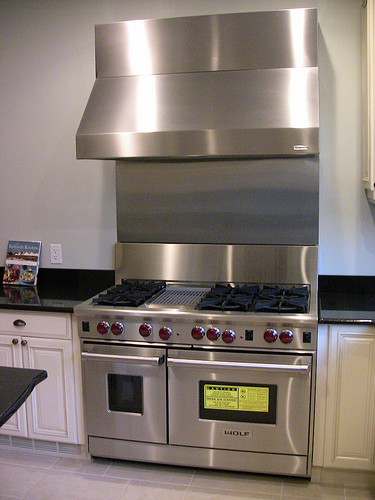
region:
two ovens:
[89, 342, 320, 434]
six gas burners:
[127, 265, 320, 353]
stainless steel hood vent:
[105, 100, 326, 193]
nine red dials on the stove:
[87, 317, 295, 350]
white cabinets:
[5, 335, 78, 455]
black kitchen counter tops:
[7, 355, 63, 422]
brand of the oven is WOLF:
[209, 405, 262, 450]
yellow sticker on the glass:
[193, 380, 300, 413]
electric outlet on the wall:
[35, 237, 75, 269]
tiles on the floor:
[68, 452, 138, 497]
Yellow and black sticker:
[197, 374, 299, 439]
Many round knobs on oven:
[96, 314, 303, 353]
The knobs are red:
[85, 314, 300, 352]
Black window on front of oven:
[95, 361, 161, 426]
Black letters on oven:
[208, 413, 271, 443]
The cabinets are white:
[5, 308, 113, 455]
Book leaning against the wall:
[2, 235, 53, 297]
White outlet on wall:
[40, 233, 68, 270]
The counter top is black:
[25, 257, 116, 323]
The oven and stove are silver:
[63, 29, 314, 415]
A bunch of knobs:
[92, 317, 295, 347]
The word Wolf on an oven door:
[216, 425, 253, 436]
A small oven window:
[102, 366, 147, 411]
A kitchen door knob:
[19, 338, 26, 344]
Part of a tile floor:
[0, 447, 175, 497]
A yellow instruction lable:
[202, 380, 272, 416]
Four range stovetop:
[195, 276, 311, 317]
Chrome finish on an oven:
[172, 380, 196, 423]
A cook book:
[2, 238, 44, 289]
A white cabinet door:
[20, 337, 81, 447]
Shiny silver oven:
[91, 264, 283, 491]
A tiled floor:
[40, 461, 81, 498]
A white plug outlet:
[38, 245, 61, 267]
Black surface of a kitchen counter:
[327, 296, 365, 335]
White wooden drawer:
[11, 311, 67, 337]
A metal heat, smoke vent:
[85, 36, 316, 166]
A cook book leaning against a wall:
[6, 217, 60, 289]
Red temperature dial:
[218, 329, 239, 345]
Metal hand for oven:
[173, 362, 318, 375]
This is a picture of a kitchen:
[30, 200, 374, 492]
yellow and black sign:
[202, 385, 278, 418]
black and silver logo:
[217, 424, 260, 447]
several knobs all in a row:
[93, 317, 297, 347]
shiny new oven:
[78, 241, 329, 483]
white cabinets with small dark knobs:
[1, 332, 78, 449]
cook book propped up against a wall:
[6, 236, 42, 286]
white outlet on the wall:
[48, 237, 70, 265]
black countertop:
[322, 272, 374, 323]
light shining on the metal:
[122, 25, 164, 133]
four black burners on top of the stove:
[198, 277, 310, 323]